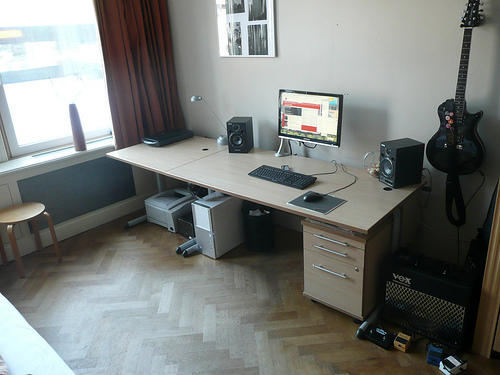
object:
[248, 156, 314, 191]
keyboard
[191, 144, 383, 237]
table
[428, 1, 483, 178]
guitar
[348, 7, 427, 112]
wall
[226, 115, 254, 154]
speaker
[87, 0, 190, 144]
curtain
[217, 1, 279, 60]
pictures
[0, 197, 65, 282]
stool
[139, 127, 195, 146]
scanner